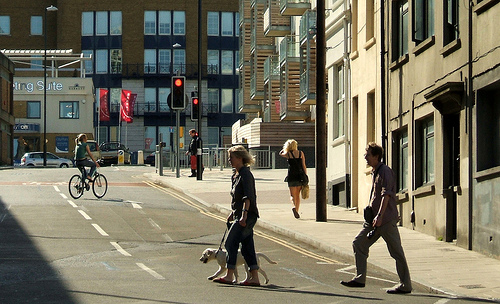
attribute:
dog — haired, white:
[200, 249, 275, 283]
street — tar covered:
[1, 167, 461, 303]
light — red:
[171, 76, 185, 110]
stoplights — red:
[171, 76, 198, 120]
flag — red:
[120, 90, 131, 123]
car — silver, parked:
[21, 152, 72, 167]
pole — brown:
[315, 0, 326, 223]